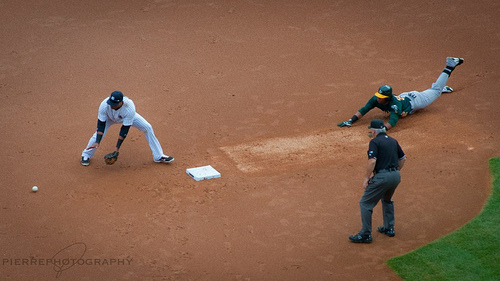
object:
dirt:
[1, 0, 500, 281]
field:
[0, 0, 499, 281]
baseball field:
[0, 0, 499, 281]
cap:
[106, 91, 123, 107]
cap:
[368, 119, 384, 129]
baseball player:
[337, 56, 465, 138]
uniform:
[80, 90, 175, 166]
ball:
[31, 186, 38, 192]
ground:
[0, 0, 499, 281]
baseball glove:
[103, 151, 119, 166]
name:
[2, 258, 133, 266]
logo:
[0, 242, 133, 281]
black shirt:
[367, 132, 406, 172]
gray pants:
[358, 168, 401, 235]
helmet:
[374, 84, 392, 98]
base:
[185, 164, 221, 181]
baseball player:
[80, 90, 175, 166]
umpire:
[348, 119, 406, 243]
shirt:
[357, 94, 413, 128]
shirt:
[97, 96, 136, 126]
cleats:
[446, 57, 465, 66]